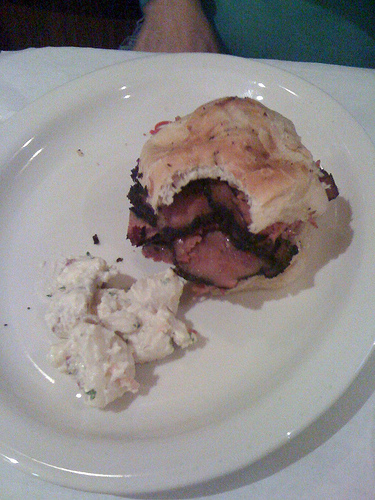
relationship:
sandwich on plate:
[124, 93, 340, 292] [7, 78, 361, 480]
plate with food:
[3, 48, 363, 494] [44, 249, 199, 407]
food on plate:
[44, 249, 199, 407] [3, 48, 363, 494]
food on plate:
[44, 249, 199, 407] [7, 78, 361, 480]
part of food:
[86, 386, 98, 401] [48, 254, 193, 411]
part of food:
[189, 326, 197, 336] [43, 250, 201, 408]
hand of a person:
[134, 3, 221, 56] [118, 2, 355, 59]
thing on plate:
[152, 121, 169, 131] [3, 48, 363, 494]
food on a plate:
[44, 249, 199, 407] [3, 48, 363, 494]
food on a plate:
[110, 87, 341, 309] [3, 48, 363, 494]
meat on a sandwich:
[161, 181, 254, 288] [124, 93, 340, 292]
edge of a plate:
[251, 444, 285, 458] [3, 48, 363, 494]